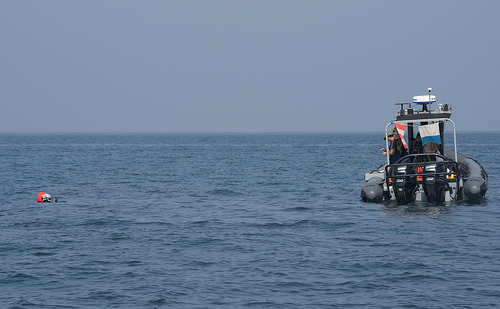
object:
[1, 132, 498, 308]
ocean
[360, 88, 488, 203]
boat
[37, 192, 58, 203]
float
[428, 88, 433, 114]
antenna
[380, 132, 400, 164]
man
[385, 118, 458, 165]
pole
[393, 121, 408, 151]
flag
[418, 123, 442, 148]
flag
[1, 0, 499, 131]
sky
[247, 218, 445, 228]
waves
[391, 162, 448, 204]
motor